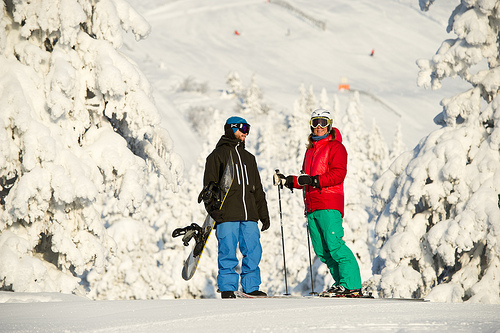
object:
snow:
[100, 316, 399, 333]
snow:
[27, 137, 67, 177]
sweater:
[204, 135, 269, 222]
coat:
[285, 127, 348, 218]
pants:
[306, 210, 363, 290]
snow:
[202, 298, 456, 321]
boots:
[217, 289, 267, 299]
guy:
[197, 116, 270, 299]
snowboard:
[181, 151, 234, 281]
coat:
[198, 135, 270, 231]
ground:
[0, 291, 500, 333]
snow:
[7, 308, 115, 327]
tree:
[371, 0, 500, 303]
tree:
[0, 0, 184, 299]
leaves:
[415, 39, 483, 91]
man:
[272, 108, 363, 294]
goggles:
[238, 122, 250, 135]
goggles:
[310, 117, 333, 128]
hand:
[273, 173, 292, 186]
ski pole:
[274, 169, 291, 296]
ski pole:
[299, 170, 317, 297]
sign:
[339, 84, 350, 90]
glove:
[297, 174, 317, 188]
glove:
[260, 215, 271, 231]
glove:
[209, 207, 224, 223]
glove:
[273, 173, 286, 186]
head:
[310, 108, 334, 136]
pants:
[215, 221, 263, 293]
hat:
[224, 116, 247, 137]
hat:
[311, 109, 331, 120]